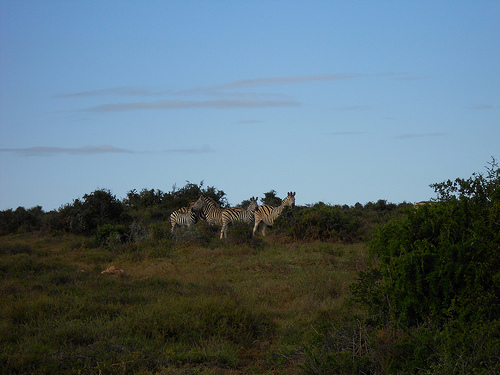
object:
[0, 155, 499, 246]
background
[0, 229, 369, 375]
field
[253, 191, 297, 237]
herd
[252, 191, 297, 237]
zebra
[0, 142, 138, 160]
cloud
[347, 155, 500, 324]
bush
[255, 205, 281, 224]
stripes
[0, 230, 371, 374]
grass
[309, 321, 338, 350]
branch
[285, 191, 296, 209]
head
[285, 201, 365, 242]
bush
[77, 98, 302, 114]
cloud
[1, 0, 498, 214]
sky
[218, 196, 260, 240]
zebra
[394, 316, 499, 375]
bush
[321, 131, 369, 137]
cloud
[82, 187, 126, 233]
trees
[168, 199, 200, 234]
zebras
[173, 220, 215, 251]
shrub